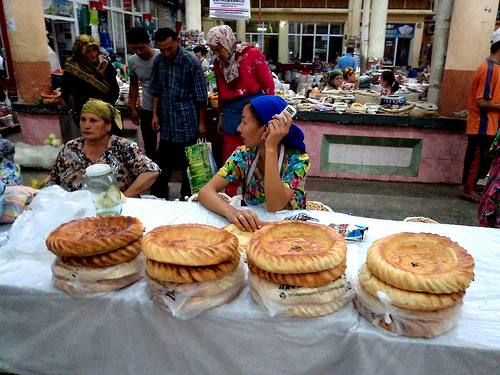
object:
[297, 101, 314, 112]
foil packaging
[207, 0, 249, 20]
sign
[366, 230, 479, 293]
bread product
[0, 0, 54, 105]
column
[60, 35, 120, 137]
woman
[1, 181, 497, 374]
table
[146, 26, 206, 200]
man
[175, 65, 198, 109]
bag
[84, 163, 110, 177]
white lid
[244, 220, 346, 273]
bread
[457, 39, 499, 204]
man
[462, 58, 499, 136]
shirt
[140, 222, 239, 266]
bread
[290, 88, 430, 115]
food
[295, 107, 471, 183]
table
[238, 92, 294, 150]
head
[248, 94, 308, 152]
scarf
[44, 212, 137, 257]
bread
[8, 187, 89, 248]
bag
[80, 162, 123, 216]
jar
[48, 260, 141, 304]
wrapper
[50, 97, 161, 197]
woman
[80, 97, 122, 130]
scarf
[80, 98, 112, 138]
head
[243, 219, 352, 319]
stack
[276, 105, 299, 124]
cell phone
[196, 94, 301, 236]
woman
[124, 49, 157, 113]
t-shirt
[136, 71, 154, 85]
stripe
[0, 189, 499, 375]
table cloth